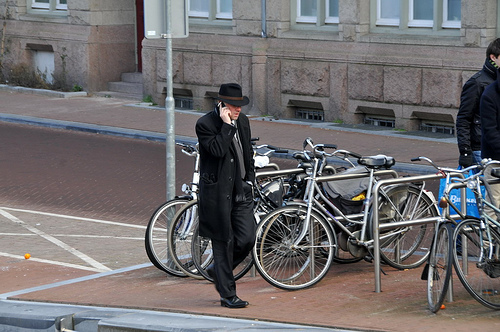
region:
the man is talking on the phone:
[195, 85, 286, 328]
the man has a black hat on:
[185, 65, 260, 112]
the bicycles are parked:
[246, 136, 496, 256]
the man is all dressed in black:
[184, 115, 276, 306]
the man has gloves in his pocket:
[191, 171, 227, 202]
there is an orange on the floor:
[14, 240, 45, 267]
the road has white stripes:
[36, 208, 122, 270]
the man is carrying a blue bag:
[446, 144, 498, 221]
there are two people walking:
[445, 60, 497, 155]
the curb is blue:
[74, 112, 155, 146]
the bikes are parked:
[172, 110, 484, 295]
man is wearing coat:
[168, 102, 278, 245]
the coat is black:
[161, 95, 258, 256]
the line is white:
[29, 225, 120, 287]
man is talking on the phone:
[191, 90, 272, 182]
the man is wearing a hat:
[197, 70, 263, 145]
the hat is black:
[186, 60, 257, 131]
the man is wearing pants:
[165, 151, 263, 321]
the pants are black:
[186, 175, 284, 298]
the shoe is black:
[193, 256, 263, 328]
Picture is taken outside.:
[1, 10, 485, 312]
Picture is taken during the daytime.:
[19, 6, 495, 327]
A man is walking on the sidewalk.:
[182, 42, 244, 327]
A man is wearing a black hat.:
[188, 69, 254, 145]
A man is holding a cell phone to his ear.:
[210, 77, 278, 132]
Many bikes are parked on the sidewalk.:
[138, 101, 484, 304]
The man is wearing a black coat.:
[189, 101, 282, 249]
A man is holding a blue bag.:
[452, 30, 491, 209]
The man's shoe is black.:
[209, 260, 286, 328]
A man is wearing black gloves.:
[441, 121, 498, 193]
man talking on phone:
[182, 66, 270, 312]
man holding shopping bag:
[418, 26, 498, 267]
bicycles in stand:
[260, 127, 443, 297]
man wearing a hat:
[188, 71, 295, 324]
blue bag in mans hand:
[431, 150, 490, 231]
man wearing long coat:
[182, 93, 282, 258]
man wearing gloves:
[456, 136, 476, 178]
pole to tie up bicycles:
[363, 169, 498, 304]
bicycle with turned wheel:
[402, 145, 471, 306]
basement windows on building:
[155, 78, 482, 143]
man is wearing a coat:
[195, 68, 283, 323]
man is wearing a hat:
[211, 77, 266, 117]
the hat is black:
[219, 82, 274, 116]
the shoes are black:
[181, 268, 263, 320]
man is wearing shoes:
[213, 284, 264, 325]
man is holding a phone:
[205, 85, 252, 133]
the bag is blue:
[427, 167, 497, 218]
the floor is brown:
[18, 137, 143, 207]